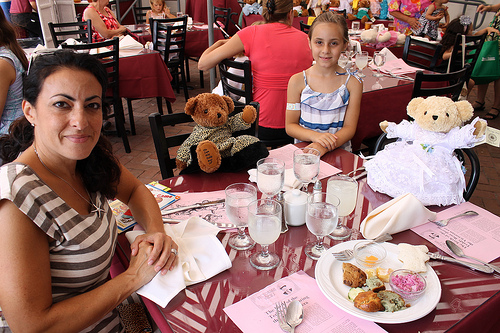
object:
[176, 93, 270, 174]
bear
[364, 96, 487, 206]
bear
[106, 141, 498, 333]
table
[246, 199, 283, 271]
glasses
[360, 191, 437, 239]
napkin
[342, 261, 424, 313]
food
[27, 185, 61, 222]
brown stripe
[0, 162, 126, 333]
on shirt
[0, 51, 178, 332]
woman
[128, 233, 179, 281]
hands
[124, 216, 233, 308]
napkins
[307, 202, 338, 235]
water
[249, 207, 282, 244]
water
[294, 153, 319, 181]
water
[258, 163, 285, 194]
water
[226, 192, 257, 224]
water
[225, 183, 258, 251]
glasses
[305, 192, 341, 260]
glasses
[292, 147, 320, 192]
glasses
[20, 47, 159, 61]
table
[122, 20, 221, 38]
table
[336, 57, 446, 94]
table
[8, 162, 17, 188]
brown stripe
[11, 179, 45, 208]
brown stripe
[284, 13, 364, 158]
kid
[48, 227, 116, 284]
stripe